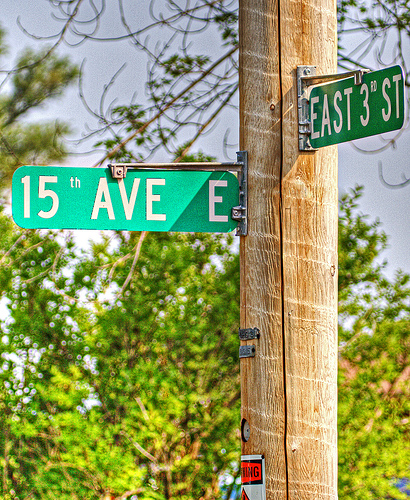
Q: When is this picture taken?
A: During the day.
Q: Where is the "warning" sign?
A: On the pole.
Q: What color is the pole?
A: Beige and brown.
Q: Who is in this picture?
A: No one.